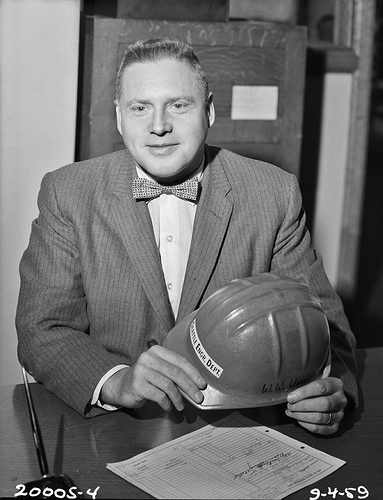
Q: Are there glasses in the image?
A: No, there are no glasses.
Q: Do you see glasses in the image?
A: No, there are no glasses.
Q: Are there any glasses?
A: No, there are no glasses.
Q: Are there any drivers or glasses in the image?
A: No, there are no glasses or drivers.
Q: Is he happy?
A: Yes, the man is happy.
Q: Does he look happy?
A: Yes, the man is happy.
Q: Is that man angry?
A: No, the man is happy.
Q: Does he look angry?
A: No, the man is happy.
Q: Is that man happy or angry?
A: The man is happy.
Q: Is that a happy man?
A: Yes, that is a happy man.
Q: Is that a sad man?
A: No, that is a happy man.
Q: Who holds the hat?
A: The man holds the hat.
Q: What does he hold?
A: The man holds the hat.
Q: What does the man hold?
A: The man holds the hat.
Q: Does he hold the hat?
A: Yes, the man holds the hat.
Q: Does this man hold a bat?
A: No, the man holds the hat.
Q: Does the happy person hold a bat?
A: No, the man holds the hat.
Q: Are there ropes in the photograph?
A: No, there are no ropes.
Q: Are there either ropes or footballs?
A: No, there are no ropes or footballs.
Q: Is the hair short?
A: Yes, the hair is short.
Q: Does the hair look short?
A: Yes, the hair is short.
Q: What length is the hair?
A: The hair is short.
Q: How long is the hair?
A: The hair is short.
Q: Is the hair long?
A: No, the hair is short.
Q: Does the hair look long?
A: No, the hair is short.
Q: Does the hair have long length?
A: No, the hair is short.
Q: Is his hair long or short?
A: The hair is short.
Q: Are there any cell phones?
A: No, there are no cell phones.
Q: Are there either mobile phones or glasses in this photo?
A: No, there are no mobile phones or glasses.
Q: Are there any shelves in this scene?
A: No, there are no shelves.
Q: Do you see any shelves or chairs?
A: No, there are no shelves or chairs.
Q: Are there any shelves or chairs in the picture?
A: No, there are no shelves or chairs.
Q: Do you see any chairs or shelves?
A: No, there are no shelves or chairs.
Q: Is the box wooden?
A: Yes, the box is wooden.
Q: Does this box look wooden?
A: Yes, the box is wooden.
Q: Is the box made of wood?
A: Yes, the box is made of wood.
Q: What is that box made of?
A: The box is made of wood.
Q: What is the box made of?
A: The box is made of wood.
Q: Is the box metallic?
A: No, the box is wooden.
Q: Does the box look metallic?
A: No, the box is wooden.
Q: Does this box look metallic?
A: No, the box is wooden.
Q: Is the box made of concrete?
A: No, the box is made of wood.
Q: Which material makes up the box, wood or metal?
A: The box is made of wood.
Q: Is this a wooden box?
A: Yes, this is a wooden box.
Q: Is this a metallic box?
A: No, this is a wooden box.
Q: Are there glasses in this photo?
A: No, there are no glasses.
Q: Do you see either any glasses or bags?
A: No, there are no glasses or bags.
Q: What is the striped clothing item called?
A: The clothing item is a blazer.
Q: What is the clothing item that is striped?
A: The clothing item is a blazer.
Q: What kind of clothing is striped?
A: The clothing is a blazer.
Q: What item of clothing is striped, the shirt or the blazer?
A: The blazer is striped.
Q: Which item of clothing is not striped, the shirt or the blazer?
A: The shirt is not striped.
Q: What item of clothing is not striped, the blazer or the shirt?
A: The shirt is not striped.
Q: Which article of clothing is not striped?
A: The clothing item is a shirt.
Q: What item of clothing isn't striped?
A: The clothing item is a shirt.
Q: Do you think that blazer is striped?
A: Yes, the blazer is striped.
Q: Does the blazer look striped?
A: Yes, the blazer is striped.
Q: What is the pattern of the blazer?
A: The blazer is striped.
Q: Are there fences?
A: No, there are no fences.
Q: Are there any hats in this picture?
A: Yes, there is a hat.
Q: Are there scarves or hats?
A: Yes, there is a hat.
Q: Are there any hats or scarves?
A: Yes, there is a hat.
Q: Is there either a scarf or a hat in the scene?
A: Yes, there is a hat.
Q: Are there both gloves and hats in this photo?
A: No, there is a hat but no gloves.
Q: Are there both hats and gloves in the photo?
A: No, there is a hat but no gloves.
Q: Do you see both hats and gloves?
A: No, there is a hat but no gloves.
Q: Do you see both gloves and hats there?
A: No, there is a hat but no gloves.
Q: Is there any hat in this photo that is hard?
A: Yes, there is a hard hat.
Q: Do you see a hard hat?
A: Yes, there is a hard hat.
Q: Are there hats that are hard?
A: Yes, there is a hat that is hard.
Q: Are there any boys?
A: No, there are no boys.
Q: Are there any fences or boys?
A: No, there are no boys or fences.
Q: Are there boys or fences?
A: No, there are no boys or fences.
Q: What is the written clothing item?
A: The clothing item is a hat.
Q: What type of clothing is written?
A: The clothing is a hat.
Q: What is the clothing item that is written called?
A: The clothing item is a hat.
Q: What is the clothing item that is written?
A: The clothing item is a hat.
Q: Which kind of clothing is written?
A: The clothing is a hat.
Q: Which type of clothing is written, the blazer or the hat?
A: The hat is written.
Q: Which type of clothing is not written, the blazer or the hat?
A: The blazer is not written.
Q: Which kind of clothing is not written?
A: The clothing is a blazer.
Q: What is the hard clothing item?
A: The clothing item is a hat.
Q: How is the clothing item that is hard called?
A: The clothing item is a hat.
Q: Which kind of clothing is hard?
A: The clothing is a hat.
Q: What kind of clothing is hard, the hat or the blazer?
A: The hat is hard.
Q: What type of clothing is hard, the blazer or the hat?
A: The hat is hard.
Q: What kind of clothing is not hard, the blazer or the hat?
A: The blazer is not hard.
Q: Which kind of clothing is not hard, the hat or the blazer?
A: The blazer is not hard.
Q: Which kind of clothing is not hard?
A: The clothing is a blazer.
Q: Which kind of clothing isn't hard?
A: The clothing is a blazer.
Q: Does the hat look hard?
A: Yes, the hat is hard.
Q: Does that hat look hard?
A: Yes, the hat is hard.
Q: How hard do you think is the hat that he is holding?
A: The hat is hard.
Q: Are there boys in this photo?
A: No, there are no boys.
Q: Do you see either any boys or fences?
A: No, there are no boys or fences.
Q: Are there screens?
A: No, there are no screens.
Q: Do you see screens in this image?
A: No, there are no screens.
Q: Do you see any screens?
A: No, there are no screens.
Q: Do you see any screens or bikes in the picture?
A: No, there are no screens or bikes.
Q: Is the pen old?
A: Yes, the pen is old.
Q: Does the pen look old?
A: Yes, the pen is old.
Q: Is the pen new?
A: No, the pen is old.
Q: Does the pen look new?
A: No, the pen is old.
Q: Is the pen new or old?
A: The pen is old.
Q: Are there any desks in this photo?
A: Yes, there is a desk.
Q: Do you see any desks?
A: Yes, there is a desk.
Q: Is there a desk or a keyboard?
A: Yes, there is a desk.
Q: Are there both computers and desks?
A: No, there is a desk but no computers.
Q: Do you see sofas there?
A: No, there are no sofas.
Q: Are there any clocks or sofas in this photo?
A: No, there are no sofas or clocks.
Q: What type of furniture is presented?
A: The furniture is a desk.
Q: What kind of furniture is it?
A: The piece of furniture is a desk.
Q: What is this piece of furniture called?
A: This is a desk.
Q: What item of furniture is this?
A: This is a desk.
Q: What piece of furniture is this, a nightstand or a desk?
A: This is a desk.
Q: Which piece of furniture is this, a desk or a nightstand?
A: This is a desk.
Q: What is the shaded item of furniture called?
A: The piece of furniture is a desk.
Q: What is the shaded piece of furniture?
A: The piece of furniture is a desk.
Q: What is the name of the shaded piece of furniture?
A: The piece of furniture is a desk.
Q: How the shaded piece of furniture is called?
A: The piece of furniture is a desk.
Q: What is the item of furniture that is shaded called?
A: The piece of furniture is a desk.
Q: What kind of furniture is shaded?
A: The furniture is a desk.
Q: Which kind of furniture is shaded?
A: The furniture is a desk.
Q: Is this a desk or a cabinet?
A: This is a desk.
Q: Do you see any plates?
A: No, there are no plates.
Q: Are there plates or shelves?
A: No, there are no plates or shelves.